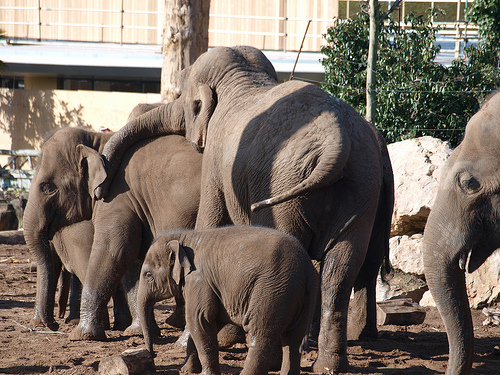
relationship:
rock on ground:
[96, 346, 156, 375] [1, 244, 498, 373]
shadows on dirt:
[362, 327, 498, 370] [0, 246, 498, 371]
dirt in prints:
[0, 246, 498, 371] [67, 355, 104, 373]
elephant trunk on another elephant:
[91, 94, 181, 200] [24, 128, 214, 338]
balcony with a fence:
[0, 0, 499, 80] [0, 0, 478, 59]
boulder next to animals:
[385, 134, 453, 237] [22, 46, 498, 373]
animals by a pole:
[22, 46, 499, 374] [160, 0, 210, 106]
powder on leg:
[76, 286, 98, 332] [68, 215, 134, 338]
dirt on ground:
[30, 341, 76, 365] [1, 244, 498, 373]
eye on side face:
[452, 171, 483, 192] [451, 90, 497, 268]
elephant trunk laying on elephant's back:
[91, 101, 185, 200] [100, 126, 200, 188]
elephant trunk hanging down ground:
[22, 202, 58, 331] [1, 244, 498, 373]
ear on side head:
[164, 240, 181, 289] [143, 233, 183, 301]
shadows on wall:
[1, 91, 92, 169] [3, 89, 160, 169]